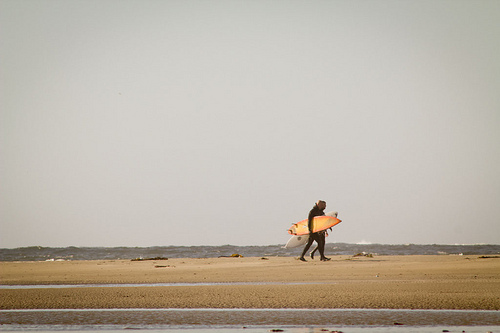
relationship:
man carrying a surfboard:
[298, 200, 328, 263] [283, 205, 347, 237]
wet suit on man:
[302, 202, 328, 252] [305, 200, 332, 265]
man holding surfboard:
[296, 200, 336, 262] [288, 212, 339, 234]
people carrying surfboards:
[297, 184, 332, 279] [268, 211, 355, 243]